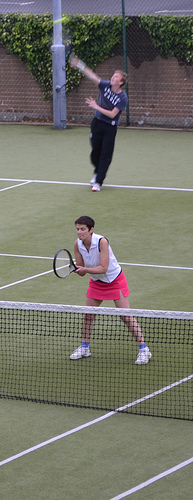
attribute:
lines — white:
[1, 171, 191, 266]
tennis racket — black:
[52, 247, 77, 278]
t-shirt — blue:
[92, 77, 129, 126]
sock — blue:
[136, 340, 146, 349]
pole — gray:
[50, 0, 65, 127]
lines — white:
[20, 250, 59, 284]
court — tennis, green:
[1, 124, 192, 499]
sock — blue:
[80, 341, 90, 347]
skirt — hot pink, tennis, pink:
[86, 268, 129, 299]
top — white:
[64, 232, 129, 286]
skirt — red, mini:
[82, 272, 136, 299]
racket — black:
[50, 245, 80, 280]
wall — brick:
[1, 11, 190, 130]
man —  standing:
[70, 55, 128, 190]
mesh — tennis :
[0, 298, 191, 423]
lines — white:
[34, 167, 158, 200]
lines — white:
[0, 176, 192, 499]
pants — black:
[90, 118, 116, 182]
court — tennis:
[66, 134, 193, 396]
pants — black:
[83, 119, 117, 183]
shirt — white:
[52, 218, 152, 367]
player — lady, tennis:
[51, 216, 152, 368]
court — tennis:
[11, 161, 190, 497]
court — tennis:
[8, 118, 154, 498]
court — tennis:
[6, 123, 173, 496]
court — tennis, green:
[15, 132, 189, 457]